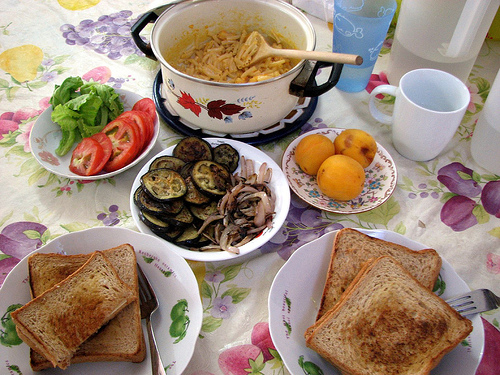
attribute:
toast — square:
[305, 253, 473, 374]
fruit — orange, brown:
[317, 154, 365, 202]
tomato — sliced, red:
[68, 98, 157, 177]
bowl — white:
[30, 87, 161, 180]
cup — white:
[368, 68, 471, 161]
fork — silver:
[445, 289, 500, 316]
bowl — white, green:
[268, 228, 486, 374]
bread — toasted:
[304, 228, 475, 374]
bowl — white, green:
[1, 226, 204, 374]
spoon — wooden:
[238, 30, 364, 67]